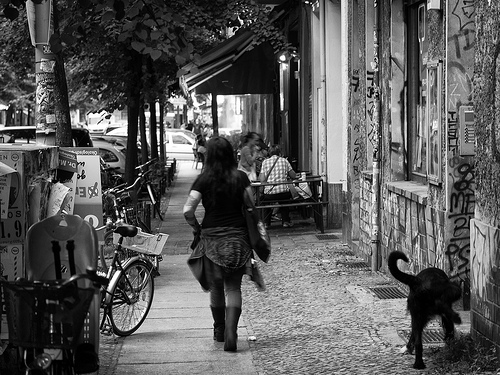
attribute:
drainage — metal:
[343, 242, 426, 328]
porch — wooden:
[163, 31, 328, 219]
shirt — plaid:
[252, 155, 298, 203]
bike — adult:
[89, 214, 169, 336]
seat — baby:
[18, 210, 117, 357]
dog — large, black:
[387, 249, 464, 370]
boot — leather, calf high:
[224, 304, 239, 354]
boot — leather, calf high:
[211, 303, 228, 342]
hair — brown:
[200, 135, 243, 199]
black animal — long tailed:
[381, 231, 483, 371]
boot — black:
[223, 302, 242, 350]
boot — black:
[206, 304, 226, 340]